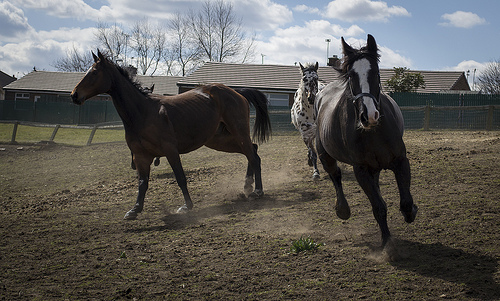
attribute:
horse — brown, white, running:
[48, 50, 302, 226]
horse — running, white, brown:
[64, 66, 308, 218]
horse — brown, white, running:
[267, 40, 434, 282]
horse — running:
[67, 47, 274, 224]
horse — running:
[290, 59, 336, 182]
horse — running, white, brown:
[308, 37, 418, 249]